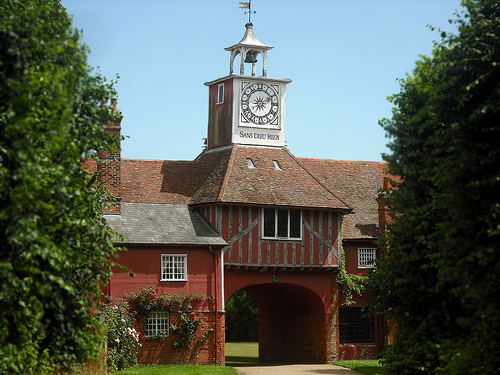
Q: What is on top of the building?
A: Weather vane.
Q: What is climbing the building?
A: Roses.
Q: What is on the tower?
A: Clock.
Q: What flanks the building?
A: Hedge.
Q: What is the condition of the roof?
A: Old.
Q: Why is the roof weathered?
A: Old.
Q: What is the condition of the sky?
A: Clear.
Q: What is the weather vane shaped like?
A: Flag.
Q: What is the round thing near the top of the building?
A: Clock.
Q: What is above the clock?
A: Bell.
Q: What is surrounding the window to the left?
A: Rose bush.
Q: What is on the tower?
A: A clock.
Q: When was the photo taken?
A: Daytime.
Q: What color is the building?
A: Maroon.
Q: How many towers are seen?
A: One.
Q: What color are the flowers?
A: Red.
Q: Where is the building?
A: In a farm.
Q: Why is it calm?
A: There is no wind.